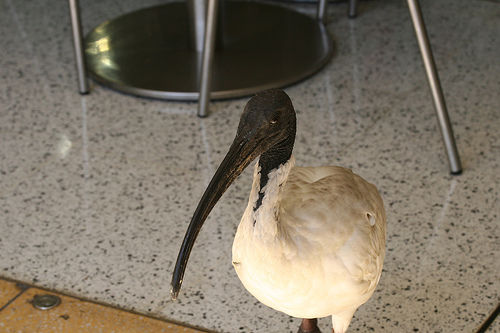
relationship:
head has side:
[222, 82, 309, 189] [249, 97, 291, 146]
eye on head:
[269, 114, 281, 124] [222, 82, 309, 189]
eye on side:
[269, 114, 281, 124] [249, 97, 291, 146]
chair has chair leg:
[54, 0, 477, 189] [407, 0, 463, 174]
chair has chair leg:
[54, 0, 477, 189] [196, 0, 218, 117]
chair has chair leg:
[54, 0, 477, 189] [66, 0, 89, 95]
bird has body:
[168, 87, 388, 332] [230, 162, 388, 318]